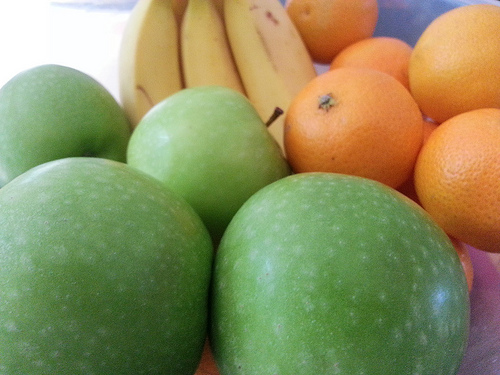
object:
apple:
[127, 85, 297, 235]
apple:
[210, 171, 472, 374]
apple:
[0, 157, 216, 374]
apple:
[2, 63, 130, 187]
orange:
[282, 66, 422, 189]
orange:
[413, 106, 499, 253]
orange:
[407, 5, 497, 123]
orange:
[329, 35, 412, 92]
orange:
[285, 0, 380, 66]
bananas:
[118, 0, 186, 137]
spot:
[294, 244, 302, 256]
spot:
[303, 296, 314, 313]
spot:
[333, 222, 342, 233]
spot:
[419, 244, 430, 258]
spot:
[402, 319, 413, 332]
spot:
[37, 190, 50, 202]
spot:
[119, 192, 131, 201]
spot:
[73, 189, 83, 197]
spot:
[15, 338, 41, 357]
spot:
[95, 327, 108, 338]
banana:
[180, 0, 246, 99]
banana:
[222, 0, 319, 161]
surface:
[64, 199, 158, 295]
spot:
[299, 202, 310, 212]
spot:
[379, 291, 388, 304]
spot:
[378, 211, 389, 228]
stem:
[264, 108, 285, 132]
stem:
[318, 92, 338, 112]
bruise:
[265, 9, 282, 27]